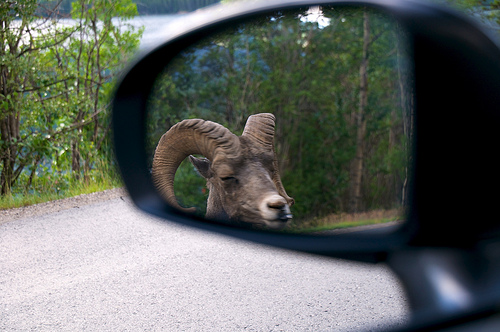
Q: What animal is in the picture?
A: A ram.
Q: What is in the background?
A: Trees.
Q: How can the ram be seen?
A: In the rear view mirror.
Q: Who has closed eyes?
A: The ram.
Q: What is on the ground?
A: A gravel road.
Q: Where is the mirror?
A: On a car.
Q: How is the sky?
A: Cloudy.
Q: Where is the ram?
A: In the road.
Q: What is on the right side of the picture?
A: The mirror.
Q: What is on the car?
A: A mirror.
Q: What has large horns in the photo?
A: The sheep.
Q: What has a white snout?
A: The sheep.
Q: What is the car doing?
A: Driving away.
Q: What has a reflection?
A: The sheep.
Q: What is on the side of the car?
A: A mirror.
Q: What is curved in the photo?
A: The Rams horn.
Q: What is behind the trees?
A: Water.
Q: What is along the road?
A: Trees.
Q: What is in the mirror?
A: Goat.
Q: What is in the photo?
A: A stag.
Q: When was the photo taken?
A: Daytime.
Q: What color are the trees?
A: Green.